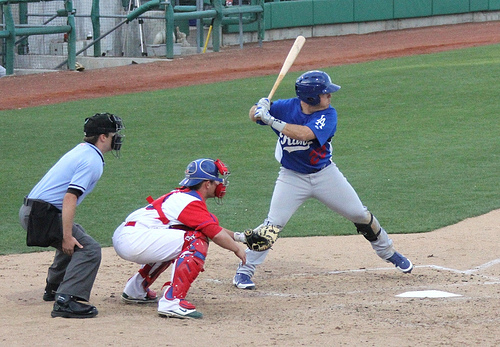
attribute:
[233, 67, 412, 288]
batter — ready, swinging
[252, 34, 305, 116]
bat — wooden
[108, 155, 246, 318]
catcher — crouching, preparing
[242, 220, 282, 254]
glove — black, white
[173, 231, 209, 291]
kneepad — here, red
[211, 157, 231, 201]
mask — protective, red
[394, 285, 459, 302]
home plate — diamond shaped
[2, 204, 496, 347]
dirt — brown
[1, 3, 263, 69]
fence — metal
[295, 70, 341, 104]
helmet — shiny, blue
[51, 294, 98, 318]
umpire — watching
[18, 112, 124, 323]
empire — bent, crouching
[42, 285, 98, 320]
shoes — black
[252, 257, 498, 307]
line — white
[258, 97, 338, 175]
jersey — blue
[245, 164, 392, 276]
pants — grey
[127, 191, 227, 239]
shirt — red, white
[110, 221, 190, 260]
pants — white